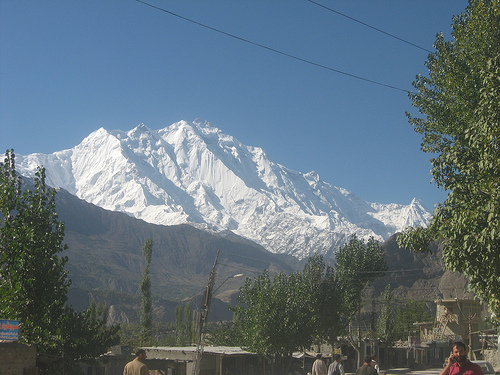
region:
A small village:
[48, 296, 497, 370]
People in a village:
[290, 340, 390, 373]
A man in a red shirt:
[435, 337, 485, 374]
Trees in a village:
[238, 253, 380, 368]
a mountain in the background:
[14, 103, 392, 320]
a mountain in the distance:
[10, 93, 437, 298]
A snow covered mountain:
[17, 103, 449, 313]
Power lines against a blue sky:
[120, 3, 495, 115]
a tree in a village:
[410, 33, 497, 327]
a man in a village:
[115, 341, 155, 373]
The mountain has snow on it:
[89, 102, 228, 206]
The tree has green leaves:
[215, 244, 380, 372]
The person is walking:
[117, 345, 155, 373]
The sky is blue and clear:
[349, 162, 454, 249]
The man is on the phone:
[441, 332, 470, 373]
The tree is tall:
[426, 7, 497, 288]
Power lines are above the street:
[132, 1, 456, 110]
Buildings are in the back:
[399, 300, 488, 372]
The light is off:
[221, 262, 250, 298]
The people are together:
[305, 354, 348, 373]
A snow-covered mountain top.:
[1, 104, 451, 266]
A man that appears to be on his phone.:
[436, 342, 486, 374]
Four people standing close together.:
[309, 350, 381, 374]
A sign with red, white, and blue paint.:
[0, 318, 22, 345]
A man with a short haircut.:
[122, 348, 153, 374]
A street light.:
[211, 268, 246, 304]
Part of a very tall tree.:
[400, 0, 497, 322]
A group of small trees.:
[235, 230, 395, 364]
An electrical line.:
[208, 257, 496, 281]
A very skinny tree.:
[138, 235, 159, 344]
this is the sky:
[29, 4, 128, 65]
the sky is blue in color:
[237, 0, 307, 35]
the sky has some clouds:
[3, 104, 65, 149]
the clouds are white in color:
[8, 104, 72, 151]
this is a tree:
[408, 1, 498, 361]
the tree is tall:
[392, 2, 497, 308]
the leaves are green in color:
[433, 64, 491, 150]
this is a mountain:
[138, 128, 213, 285]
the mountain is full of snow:
[161, 120, 199, 295]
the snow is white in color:
[161, 148, 206, 184]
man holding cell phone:
[448, 333, 478, 370]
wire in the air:
[290, 67, 421, 99]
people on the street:
[117, 352, 406, 373]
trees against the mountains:
[0, 151, 75, 354]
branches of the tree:
[381, 73, 457, 212]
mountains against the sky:
[56, 105, 269, 175]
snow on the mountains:
[20, 108, 380, 247]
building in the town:
[386, 292, 477, 365]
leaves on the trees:
[5, 161, 58, 328]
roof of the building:
[138, 341, 247, 356]